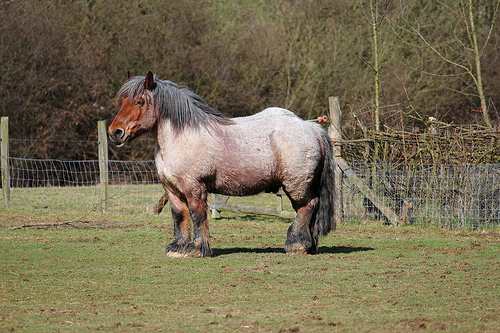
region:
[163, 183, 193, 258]
the thick brown and black leg of a horse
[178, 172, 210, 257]
the thick brown and black leg of a horse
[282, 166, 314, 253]
the thick brown and black leg of a horse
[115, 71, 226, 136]
the grey mane of the horse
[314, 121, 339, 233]
the grey tail of the horse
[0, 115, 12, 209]
a tall fence post of a fence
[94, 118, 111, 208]
a tall fence post of a fence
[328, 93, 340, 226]
a tall fence post of a fence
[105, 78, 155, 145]
the brown head of a horse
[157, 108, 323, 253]
the body of the horse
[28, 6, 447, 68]
a dense forest in the background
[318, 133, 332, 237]
a wide tail of the horse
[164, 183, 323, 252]
the four thick legs of the horse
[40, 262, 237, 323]
many grass on the ground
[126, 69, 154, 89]
the two ears of the horse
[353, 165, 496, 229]
a mesh to the right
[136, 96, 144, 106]
one eye of the horse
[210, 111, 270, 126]
the back of the horse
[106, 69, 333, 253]
a dwarf horse on the scene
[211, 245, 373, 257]
the shadow of the dwarf horse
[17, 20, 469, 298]
this is heavy looking horse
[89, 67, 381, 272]
this horse is very stout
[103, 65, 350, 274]
the horse looks larger than a normal steed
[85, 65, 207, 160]
it has a red face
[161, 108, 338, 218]
the body of this horse is white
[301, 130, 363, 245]
the horse has a long tail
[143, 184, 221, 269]
the horse has black legs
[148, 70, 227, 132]
the mane is black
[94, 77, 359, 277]
this horse is unsually large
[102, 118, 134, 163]
this horse has a big snout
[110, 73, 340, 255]
a sturdy work horse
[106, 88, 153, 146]
the broad face of a horse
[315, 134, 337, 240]
the long black tail of a horse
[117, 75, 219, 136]
the black and gray mane of a horse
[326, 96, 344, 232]
a brown wooden fence post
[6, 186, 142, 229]
a dead branch on the ground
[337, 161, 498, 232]
wire mesh fencing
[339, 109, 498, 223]
a pile of dead brambles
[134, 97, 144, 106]
the left eye of a horse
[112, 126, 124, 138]
the large left nostril of a horse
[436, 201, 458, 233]
part of a fence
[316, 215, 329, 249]
part of a tail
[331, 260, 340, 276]
part of a grass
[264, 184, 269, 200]
part of a horse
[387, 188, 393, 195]
edge of a fence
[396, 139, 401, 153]
part of a fence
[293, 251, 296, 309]
edge of a lawn